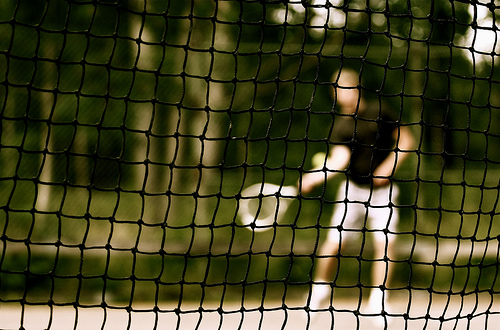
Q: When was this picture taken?
A: In the daytime.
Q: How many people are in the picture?
A: One.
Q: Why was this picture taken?
A: To show the sport of tennis.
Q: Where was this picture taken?
A: At a park.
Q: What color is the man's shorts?
A: White.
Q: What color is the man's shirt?
A: Black.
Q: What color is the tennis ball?
A: Yellow.